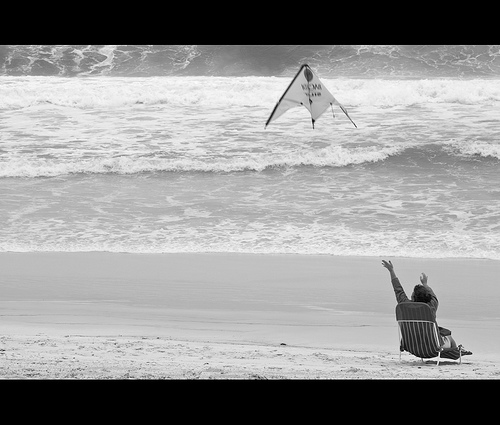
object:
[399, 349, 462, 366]
metal leg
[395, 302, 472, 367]
chair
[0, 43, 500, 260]
wavy ocean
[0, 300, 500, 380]
shore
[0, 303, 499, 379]
ground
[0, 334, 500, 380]
sand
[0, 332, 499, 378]
footprints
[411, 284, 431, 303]
head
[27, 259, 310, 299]
wet sand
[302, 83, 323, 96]
letters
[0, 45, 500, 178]
waves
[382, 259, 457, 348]
person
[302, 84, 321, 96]
logo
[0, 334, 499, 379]
area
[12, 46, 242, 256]
water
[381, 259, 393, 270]
hand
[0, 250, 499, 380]
beach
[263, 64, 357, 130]
kite